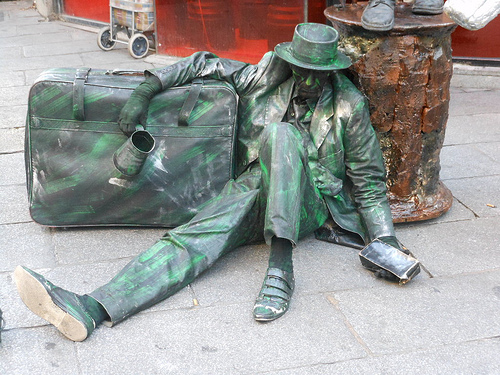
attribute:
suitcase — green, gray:
[26, 68, 243, 228]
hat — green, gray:
[274, 24, 353, 72]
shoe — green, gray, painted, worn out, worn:
[253, 266, 296, 320]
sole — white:
[11, 265, 88, 344]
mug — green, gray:
[111, 125, 156, 174]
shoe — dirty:
[359, 2, 398, 32]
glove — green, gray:
[115, 74, 165, 136]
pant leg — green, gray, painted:
[89, 180, 264, 329]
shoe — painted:
[11, 264, 98, 341]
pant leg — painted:
[257, 122, 328, 248]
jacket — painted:
[147, 49, 397, 247]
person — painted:
[12, 23, 422, 344]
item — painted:
[358, 237, 420, 286]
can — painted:
[112, 126, 157, 177]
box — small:
[358, 236, 421, 284]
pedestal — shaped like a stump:
[323, 1, 455, 226]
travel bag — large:
[23, 64, 241, 229]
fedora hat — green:
[274, 20, 353, 71]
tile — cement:
[315, 265, 499, 359]